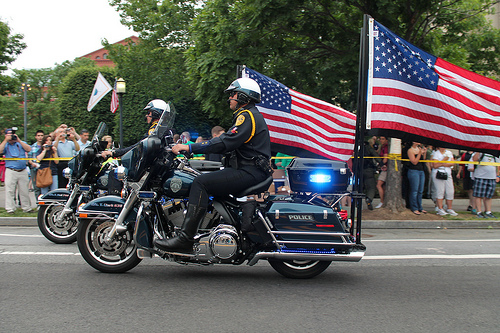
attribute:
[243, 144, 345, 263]
vehicle — emergency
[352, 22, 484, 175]
flag — american, blue, red, flying, white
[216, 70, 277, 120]
cop — riding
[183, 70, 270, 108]
helmet — green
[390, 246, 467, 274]
line — white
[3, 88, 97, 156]
man — taking, photographing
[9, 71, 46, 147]
light — tall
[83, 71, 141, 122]
flags — hanging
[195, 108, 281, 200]
uniform — police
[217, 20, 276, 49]
leaves — green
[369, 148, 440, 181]
tape — yellow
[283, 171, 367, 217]
light — blue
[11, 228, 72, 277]
lines — painted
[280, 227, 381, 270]
pipe — exhaust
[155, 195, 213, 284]
boot — black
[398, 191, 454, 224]
shoes — white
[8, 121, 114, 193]
people — crowded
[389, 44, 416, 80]
stars — white